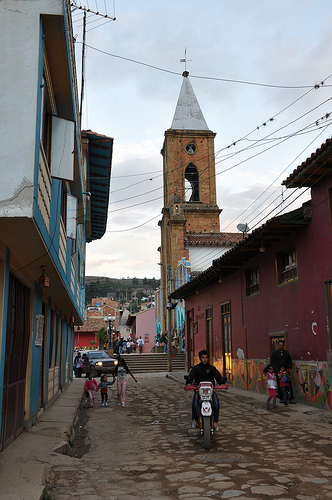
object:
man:
[186, 345, 228, 433]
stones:
[151, 420, 159, 425]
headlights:
[96, 361, 103, 367]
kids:
[96, 372, 116, 404]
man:
[270, 338, 297, 405]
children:
[262, 363, 280, 410]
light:
[114, 360, 119, 366]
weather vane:
[179, 47, 193, 64]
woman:
[112, 356, 137, 407]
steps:
[119, 354, 185, 357]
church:
[153, 46, 220, 292]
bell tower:
[157, 39, 221, 348]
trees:
[93, 325, 110, 350]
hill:
[84, 274, 158, 310]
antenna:
[71, 0, 118, 126]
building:
[0, 1, 116, 457]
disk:
[236, 223, 249, 232]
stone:
[208, 478, 235, 487]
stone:
[189, 461, 208, 470]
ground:
[0, 367, 331, 497]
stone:
[167, 419, 171, 421]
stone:
[235, 436, 247, 442]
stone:
[153, 450, 159, 453]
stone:
[183, 442, 193, 447]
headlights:
[208, 389, 211, 394]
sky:
[72, 0, 332, 277]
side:
[167, 145, 332, 407]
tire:
[203, 417, 210, 449]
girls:
[84, 369, 98, 406]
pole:
[166, 298, 172, 371]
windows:
[275, 240, 299, 286]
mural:
[291, 359, 330, 407]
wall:
[243, 285, 323, 403]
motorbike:
[183, 380, 229, 451]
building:
[166, 133, 332, 409]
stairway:
[128, 367, 186, 369]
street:
[55, 354, 329, 497]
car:
[73, 346, 121, 377]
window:
[220, 303, 230, 315]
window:
[205, 305, 213, 320]